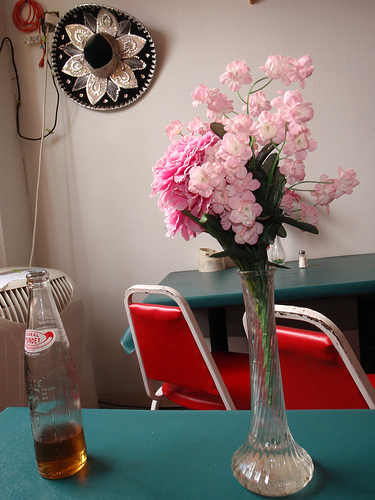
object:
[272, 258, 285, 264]
glass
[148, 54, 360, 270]
flowers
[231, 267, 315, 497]
vase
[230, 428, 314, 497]
water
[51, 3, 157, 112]
hat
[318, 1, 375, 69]
wall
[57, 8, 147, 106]
flower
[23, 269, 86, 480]
bottle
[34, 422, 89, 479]
cola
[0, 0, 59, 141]
electrical wire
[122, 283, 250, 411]
chair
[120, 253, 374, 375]
table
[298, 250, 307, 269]
salt shaker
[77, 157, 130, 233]
white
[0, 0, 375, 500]
room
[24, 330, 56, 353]
label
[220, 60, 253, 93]
flower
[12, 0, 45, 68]
cord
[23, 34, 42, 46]
tag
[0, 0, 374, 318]
background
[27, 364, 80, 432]
finished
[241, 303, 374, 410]
chairs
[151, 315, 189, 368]
plastic cushions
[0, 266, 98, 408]
heater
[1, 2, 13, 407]
corner